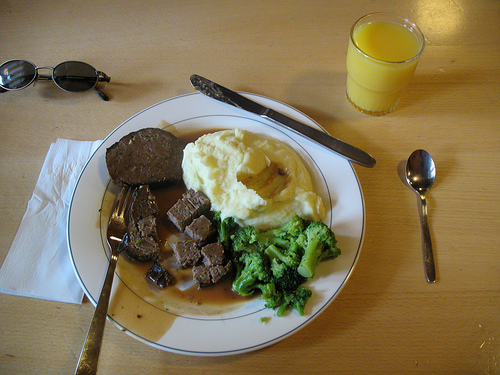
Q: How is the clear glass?
A: Full.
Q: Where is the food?
A: On the plate.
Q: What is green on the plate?
A: Broccoli.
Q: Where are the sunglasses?
A: On the table.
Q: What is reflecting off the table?
A: Light.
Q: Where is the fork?
A: On the plate.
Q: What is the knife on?
A: The plate.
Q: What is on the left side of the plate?
A: A napkin.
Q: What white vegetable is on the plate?
A: Mashed potatoes.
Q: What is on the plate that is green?
A: Broccoli.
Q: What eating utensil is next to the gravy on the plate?
A: A fork.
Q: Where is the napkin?
A: On the table.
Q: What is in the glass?
A: Orange juice.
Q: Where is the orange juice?
A: In the glass.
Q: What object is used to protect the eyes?
A: Sunglasses.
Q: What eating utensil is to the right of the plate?
A: A spoon.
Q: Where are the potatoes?
A: On the plate.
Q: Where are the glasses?
A: On the table.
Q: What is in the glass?
A: Juice.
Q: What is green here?
A: Broccoli.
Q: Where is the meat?
A: On the plate.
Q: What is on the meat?
A: Gravy.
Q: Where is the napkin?
A: By the plate.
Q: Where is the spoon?
A: On the table.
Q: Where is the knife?
A: On the plate.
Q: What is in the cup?
A: Orange juice.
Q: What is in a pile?
A: Potatoes.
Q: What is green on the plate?
A: Broccoli.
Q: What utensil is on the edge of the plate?
A: Knife.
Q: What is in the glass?
A: Juice.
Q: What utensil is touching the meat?
A: Fork.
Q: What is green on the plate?
A: Broccoli.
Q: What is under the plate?
A: A napkin.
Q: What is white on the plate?
A: Potatoes.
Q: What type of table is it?
A: Wooden.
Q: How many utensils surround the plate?
A: 3.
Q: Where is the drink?
A: Above the plate.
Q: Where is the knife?
A: On the plate.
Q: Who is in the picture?
A: No one.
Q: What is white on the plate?
A: Mashed Potatoes.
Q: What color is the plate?
A: White.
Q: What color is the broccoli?
A: Green.